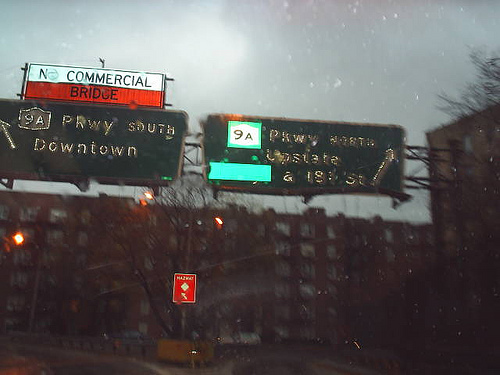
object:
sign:
[201, 113, 406, 197]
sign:
[0, 98, 188, 189]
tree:
[116, 177, 274, 336]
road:
[1, 343, 158, 373]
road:
[236, 357, 360, 374]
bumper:
[156, 338, 216, 363]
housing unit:
[2, 189, 437, 347]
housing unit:
[426, 103, 498, 374]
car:
[216, 332, 260, 346]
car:
[105, 328, 153, 340]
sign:
[21, 62, 167, 110]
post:
[446, 137, 474, 371]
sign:
[173, 272, 198, 303]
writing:
[39, 66, 153, 100]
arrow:
[180, 291, 190, 300]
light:
[14, 234, 26, 244]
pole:
[14, 233, 45, 330]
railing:
[3, 326, 157, 358]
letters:
[32, 114, 176, 158]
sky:
[0, 2, 497, 223]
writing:
[17, 106, 52, 129]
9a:
[24, 112, 46, 126]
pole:
[180, 203, 188, 338]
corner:
[138, 335, 233, 374]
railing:
[216, 342, 267, 363]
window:
[297, 243, 316, 259]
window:
[300, 223, 314, 237]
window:
[275, 281, 291, 297]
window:
[49, 209, 68, 225]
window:
[45, 229, 64, 243]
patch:
[228, 120, 263, 149]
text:
[233, 128, 254, 142]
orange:
[25, 80, 164, 106]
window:
[18, 207, 40, 221]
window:
[8, 297, 25, 311]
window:
[11, 271, 26, 287]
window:
[275, 221, 290, 237]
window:
[327, 245, 340, 259]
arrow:
[0, 120, 17, 149]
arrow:
[371, 146, 397, 183]